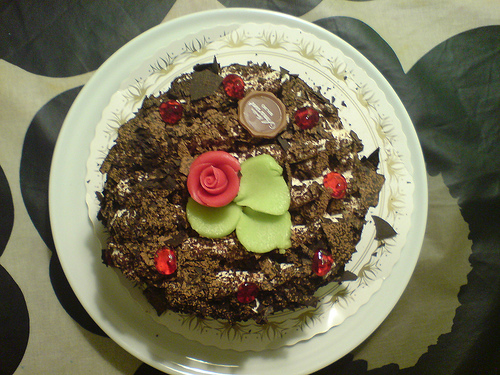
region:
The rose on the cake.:
[192, 147, 240, 212]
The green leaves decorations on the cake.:
[187, 158, 292, 253]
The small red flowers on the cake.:
[95, 80, 355, 301]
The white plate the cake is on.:
[53, 8, 423, 370]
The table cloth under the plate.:
[5, 3, 499, 373]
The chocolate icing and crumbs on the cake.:
[99, 60, 374, 320]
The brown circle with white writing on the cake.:
[239, 84, 284, 139]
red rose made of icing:
[183, 146, 239, 210]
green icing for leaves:
[235, 157, 295, 253]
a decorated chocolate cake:
[100, 52, 364, 331]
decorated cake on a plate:
[97, 48, 383, 335]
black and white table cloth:
[5, 0, 86, 365]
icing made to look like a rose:
[177, 145, 317, 260]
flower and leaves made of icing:
[180, 145, 297, 252]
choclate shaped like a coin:
[237, 80, 289, 146]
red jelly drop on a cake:
[152, 243, 181, 283]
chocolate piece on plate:
[368, 211, 398, 251]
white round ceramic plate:
[46, 6, 427, 374]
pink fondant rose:
[185, 148, 242, 206]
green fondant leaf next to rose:
[237, 154, 290, 214]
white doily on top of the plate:
[82, 22, 418, 352]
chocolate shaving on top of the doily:
[370, 214, 399, 241]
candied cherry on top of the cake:
[324, 172, 347, 199]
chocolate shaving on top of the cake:
[187, 71, 222, 101]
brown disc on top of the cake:
[235, 89, 289, 139]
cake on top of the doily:
[98, 57, 380, 324]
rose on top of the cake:
[184, 149, 243, 209]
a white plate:
[44, 7, 444, 374]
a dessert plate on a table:
[1, 3, 498, 370]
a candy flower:
[183, 148, 245, 211]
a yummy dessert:
[103, 63, 383, 337]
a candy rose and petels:
[186, 151, 302, 250]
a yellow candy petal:
[234, 150, 293, 212]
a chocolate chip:
[292, 101, 322, 130]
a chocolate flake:
[366, 208, 406, 245]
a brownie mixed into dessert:
[121, 115, 199, 157]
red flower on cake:
[321, 166, 353, 214]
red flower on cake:
[308, 249, 335, 287]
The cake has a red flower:
[168, 123, 280, 223]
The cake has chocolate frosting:
[47, 24, 449, 363]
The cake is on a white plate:
[37, 17, 441, 361]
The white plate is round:
[52, 20, 473, 361]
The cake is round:
[77, 36, 405, 353]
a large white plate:
[41, 13, 445, 372]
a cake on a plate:
[37, 10, 437, 367]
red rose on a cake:
[181, 142, 251, 214]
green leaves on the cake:
[182, 161, 297, 262]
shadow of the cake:
[76, 258, 293, 365]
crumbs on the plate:
[362, 196, 398, 269]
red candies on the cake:
[137, 69, 362, 308]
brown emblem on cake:
[225, 79, 297, 142]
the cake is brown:
[99, 49, 389, 337]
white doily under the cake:
[89, 0, 420, 346]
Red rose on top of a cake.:
[185, 150, 242, 206]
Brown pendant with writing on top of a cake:
[237, 88, 287, 137]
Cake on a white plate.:
[98, 46, 390, 323]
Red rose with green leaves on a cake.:
[183, 152, 292, 254]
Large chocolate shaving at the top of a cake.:
[164, 65, 228, 105]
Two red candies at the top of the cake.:
[156, 70, 243, 125]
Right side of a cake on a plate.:
[238, 10, 391, 365]